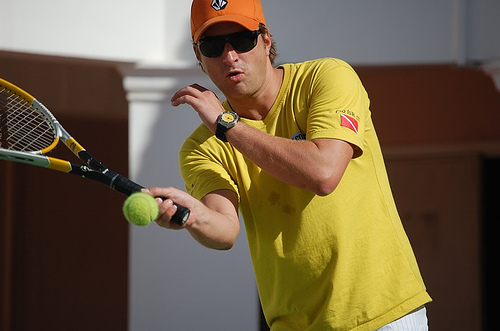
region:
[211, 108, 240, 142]
a watch on the man's wrist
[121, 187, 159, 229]
a green tennis ball in the air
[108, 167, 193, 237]
the handle of a tennis racket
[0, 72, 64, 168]
the head of a tennis racket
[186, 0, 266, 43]
an orange baseball cap on the man's head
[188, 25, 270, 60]
a black pair of sunglasses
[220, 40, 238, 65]
the nose of a man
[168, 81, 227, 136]
the hand of a man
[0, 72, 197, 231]
a tennis racket in the man's hand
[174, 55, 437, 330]
a yellow tee shirt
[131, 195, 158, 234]
a green tennis ball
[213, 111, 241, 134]
a black tied wristwatch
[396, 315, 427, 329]
part of a white pant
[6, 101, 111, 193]
part of a tennis racket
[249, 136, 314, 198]
left arm of the player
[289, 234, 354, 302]
part of a yellow top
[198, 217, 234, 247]
right arm of the player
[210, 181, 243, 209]
right bicep of the player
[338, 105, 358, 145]
a red logo on the shirt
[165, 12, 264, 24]
front part of the orange cap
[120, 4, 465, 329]
Man playing tennis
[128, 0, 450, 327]
Tennis player wears yellow shirt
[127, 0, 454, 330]
Tennis player wears orange cap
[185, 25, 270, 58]
Black sun glasses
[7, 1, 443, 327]
Player kicks a tennis ball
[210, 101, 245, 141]
Black and yellow clock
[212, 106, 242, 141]
Clock is yellow in the center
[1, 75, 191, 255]
Tennis racket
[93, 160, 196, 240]
Handle of tennis racket is black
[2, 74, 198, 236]
Tennis racket is black, tan and orange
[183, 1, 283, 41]
Man is wearing orange cap.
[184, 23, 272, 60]
Man is wearing sunglasses.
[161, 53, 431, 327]
Man is wearing yellow shirt.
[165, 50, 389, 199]
Yellow shirt has short sleeves.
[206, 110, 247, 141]
Man is wearing watch.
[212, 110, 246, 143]
Watch has a black band.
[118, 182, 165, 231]
Tennis ball is yellow.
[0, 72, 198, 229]
Man is holding tennis racquet.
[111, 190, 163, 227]
Tennis ball is in mid air.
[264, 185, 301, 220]
Shirt has two spots on it.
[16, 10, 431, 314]
A man plalying tennis.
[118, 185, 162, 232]
A yellow tennis ball.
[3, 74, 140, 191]
A black and yellow tennis racquet.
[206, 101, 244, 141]
A man's wristwatch.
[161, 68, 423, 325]
A yellow short sleeve shirt.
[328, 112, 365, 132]
A square pink and white emblem.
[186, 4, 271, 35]
An orange hat.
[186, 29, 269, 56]
A pair of black sunglasses.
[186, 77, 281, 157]
Watch is on left wrist.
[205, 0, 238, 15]
An emblem on a hat.